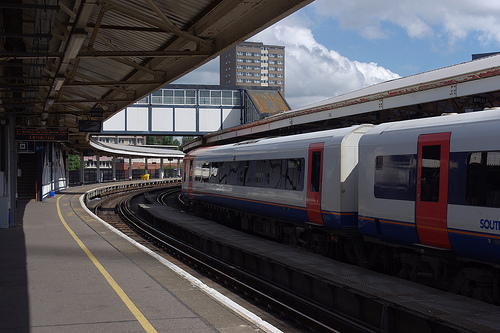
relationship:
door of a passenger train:
[184, 133, 453, 235] [177, 100, 485, 295]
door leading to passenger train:
[184, 133, 453, 235] [177, 100, 485, 295]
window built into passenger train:
[188, 151, 495, 208] [177, 100, 485, 295]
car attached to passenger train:
[176, 119, 378, 254] [177, 100, 485, 295]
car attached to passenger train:
[351, 103, 483, 285] [177, 100, 485, 295]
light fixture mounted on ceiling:
[64, 30, 87, 63] [8, 4, 300, 130]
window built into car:
[188, 151, 495, 208] [176, 119, 378, 254]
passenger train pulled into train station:
[177, 100, 485, 295] [1, 1, 484, 326]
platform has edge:
[0, 177, 500, 332] [102, 219, 158, 257]